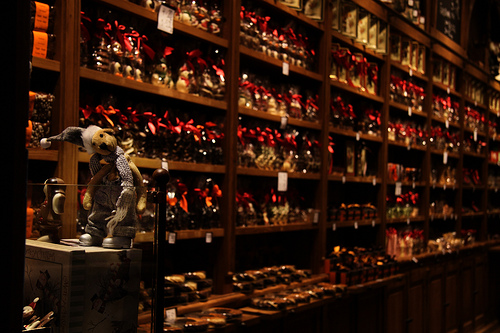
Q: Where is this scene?
A: A store.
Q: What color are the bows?
A: Red.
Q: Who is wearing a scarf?
A: The toy dog.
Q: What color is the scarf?
A: Gray.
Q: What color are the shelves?
A: Brown.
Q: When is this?
A: Night time.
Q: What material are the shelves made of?
A: Wood.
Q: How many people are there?
A: None.